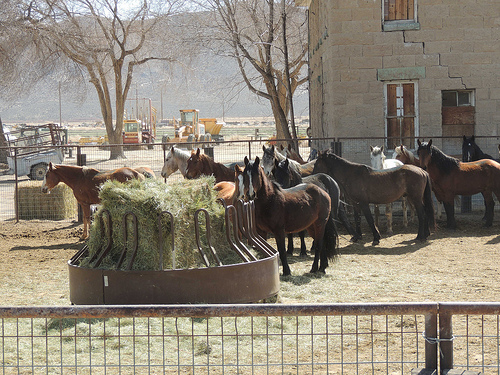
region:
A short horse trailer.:
[3, 123, 65, 179]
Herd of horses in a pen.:
[42, 138, 498, 277]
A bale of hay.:
[13, 180, 78, 220]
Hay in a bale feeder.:
[85, 175, 262, 270]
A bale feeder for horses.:
[68, 199, 280, 305]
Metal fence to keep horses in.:
[0, 302, 499, 374]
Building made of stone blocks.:
[308, 66, 499, 210]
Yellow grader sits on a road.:
[162, 110, 225, 149]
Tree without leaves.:
[1, 0, 204, 160]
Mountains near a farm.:
[0, 0, 310, 122]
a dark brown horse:
[241, 156, 333, 277]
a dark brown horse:
[414, 136, 499, 231]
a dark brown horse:
[42, 161, 144, 238]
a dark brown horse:
[185, 145, 234, 187]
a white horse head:
[157, 145, 189, 180]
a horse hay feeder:
[66, 178, 275, 311]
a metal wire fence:
[2, 305, 497, 374]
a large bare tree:
[4, 0, 194, 159]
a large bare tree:
[187, 0, 309, 150]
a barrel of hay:
[14, 180, 73, 217]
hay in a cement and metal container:
[59, 172, 269, 287]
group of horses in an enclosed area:
[16, 142, 483, 236]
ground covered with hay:
[180, 330, 297, 363]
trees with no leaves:
[38, 14, 293, 71]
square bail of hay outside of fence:
[12, 173, 85, 223]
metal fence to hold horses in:
[117, 290, 359, 365]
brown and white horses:
[253, 130, 483, 254]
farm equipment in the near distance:
[112, 88, 215, 146]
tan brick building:
[320, 18, 474, 143]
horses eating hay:
[225, 148, 278, 240]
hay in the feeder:
[105, 183, 211, 264]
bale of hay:
[8, 171, 70, 216]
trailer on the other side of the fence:
[9, 121, 50, 178]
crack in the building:
[404, 25, 475, 96]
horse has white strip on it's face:
[234, 170, 244, 200]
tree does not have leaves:
[129, 5, 240, 60]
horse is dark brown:
[348, 163, 421, 213]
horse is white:
[368, 143, 402, 172]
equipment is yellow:
[167, 102, 221, 143]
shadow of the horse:
[9, 233, 83, 258]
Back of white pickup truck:
[0, 122, 65, 177]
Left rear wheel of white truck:
[25, 160, 50, 180]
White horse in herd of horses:
[362, 138, 407, 173]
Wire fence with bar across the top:
[0, 300, 496, 370]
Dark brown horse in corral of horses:
[238, 152, 333, 282]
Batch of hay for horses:
[92, 176, 218, 266]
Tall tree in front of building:
[230, 35, 327, 162]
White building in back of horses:
[307, 35, 497, 156]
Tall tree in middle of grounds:
[30, 35, 185, 157]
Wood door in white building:
[383, 78, 420, 149]